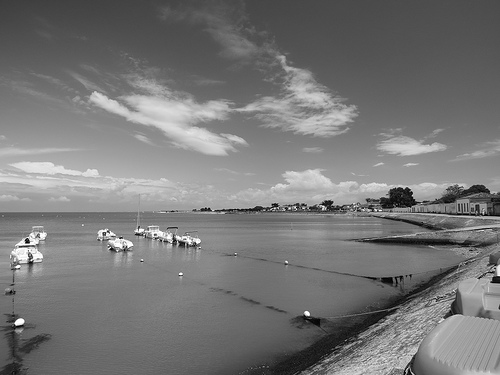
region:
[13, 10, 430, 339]
this is in black and white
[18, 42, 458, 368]
this is monochromatic style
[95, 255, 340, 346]
this is a shore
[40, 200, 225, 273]
these are boats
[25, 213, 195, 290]
the boats are sitting in the bay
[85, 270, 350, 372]
the water looks very transparent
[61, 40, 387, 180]
the weather is partly cloudy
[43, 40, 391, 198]
these clouds are white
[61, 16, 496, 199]
the weather looks very nice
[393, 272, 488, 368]
this is the beach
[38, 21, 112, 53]
white clouds in blue sky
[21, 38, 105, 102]
white clouds in blue sky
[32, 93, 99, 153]
white clouds in blue sky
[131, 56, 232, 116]
white clouds in blue sky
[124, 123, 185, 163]
white clouds in blue sky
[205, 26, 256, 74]
white clouds in blue sky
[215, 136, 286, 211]
white clouds in blue sky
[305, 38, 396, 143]
white clouds in blue sky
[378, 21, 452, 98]
white clouds in blue sky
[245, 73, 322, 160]
white clouds in blue sky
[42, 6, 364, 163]
High cloud formation in the sky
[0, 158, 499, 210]
Heavy cloud formation in the sky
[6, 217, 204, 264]
White boats on the sea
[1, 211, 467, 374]
Calm seas on the port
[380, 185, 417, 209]
Big tree in the background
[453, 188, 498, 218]
White house near the sea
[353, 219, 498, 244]
Ramp near the sea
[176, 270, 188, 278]
Small bouey on the sea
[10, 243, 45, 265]
white speed boat on the sea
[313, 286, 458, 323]
Rope hanging near the sea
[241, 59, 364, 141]
clouds in the sky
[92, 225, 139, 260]
boats on the water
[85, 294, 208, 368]
the water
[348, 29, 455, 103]
the sky is clear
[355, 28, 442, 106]
the sky is dark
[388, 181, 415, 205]
a tree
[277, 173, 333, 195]
the clouds are white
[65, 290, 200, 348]
the ocean water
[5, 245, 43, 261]
a white boat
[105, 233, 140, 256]
the boat in the water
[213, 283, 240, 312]
dark spot in water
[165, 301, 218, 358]
dark spot in water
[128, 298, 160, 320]
dark spot in water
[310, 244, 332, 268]
dark spot in water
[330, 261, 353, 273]
dark spot in water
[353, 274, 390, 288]
dark spot in water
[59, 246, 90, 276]
dark spot in water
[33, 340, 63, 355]
dark spot in water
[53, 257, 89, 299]
dark spot in water